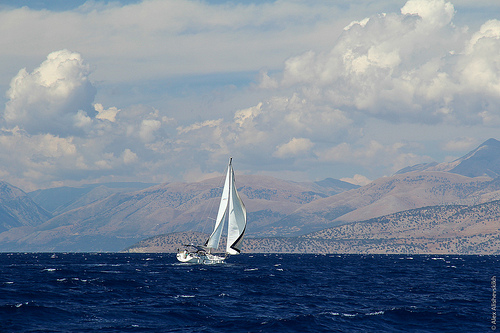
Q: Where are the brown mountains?
A: Beyond the water.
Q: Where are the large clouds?
A: In the sky.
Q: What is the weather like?
A: Cloudy.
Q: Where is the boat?
A: In the ocean.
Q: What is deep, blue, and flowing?
A: The ocean.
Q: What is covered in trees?
A: The mountains.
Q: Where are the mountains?
A: In the distance.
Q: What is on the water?
A: A small boat.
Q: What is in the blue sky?
A: A fluffy white cloud.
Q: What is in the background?
A: Tall hills.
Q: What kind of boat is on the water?
A: A sailboat.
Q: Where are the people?
A: On the sailboat.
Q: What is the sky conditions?
A: Cloudy.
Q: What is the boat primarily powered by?
A: Wind.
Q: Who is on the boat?
A: The people sailing the boat.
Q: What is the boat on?
A: The water.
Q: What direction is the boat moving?
A: To the right.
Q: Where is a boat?
A: On the ocean.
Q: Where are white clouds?
A: In the sky.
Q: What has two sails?
A: The boat.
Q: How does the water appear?
A: Blue.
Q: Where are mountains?
A: In the distance.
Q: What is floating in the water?
A: Sailboat.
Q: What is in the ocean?
A: A sailboat.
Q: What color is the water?
A: Very blue.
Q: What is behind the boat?
A: The mountains.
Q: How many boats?
A: One.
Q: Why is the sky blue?
A: It's a nice day.